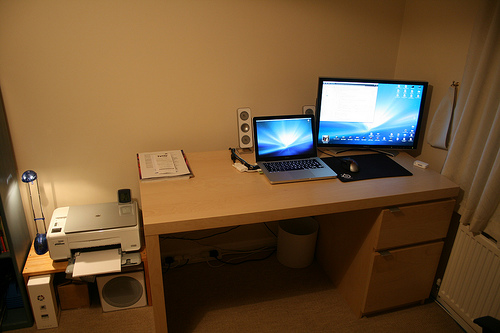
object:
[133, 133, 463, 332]
desk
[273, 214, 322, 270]
can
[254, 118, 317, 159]
monitors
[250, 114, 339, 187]
laptop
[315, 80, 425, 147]
monitor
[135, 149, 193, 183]
papers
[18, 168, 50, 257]
lamp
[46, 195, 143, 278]
printer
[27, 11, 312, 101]
wall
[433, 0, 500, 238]
curtains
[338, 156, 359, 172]
mouse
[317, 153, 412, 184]
pad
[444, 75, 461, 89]
hook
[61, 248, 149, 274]
tray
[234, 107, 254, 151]
speakers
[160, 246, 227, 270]
powerstrip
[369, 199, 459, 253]
drawers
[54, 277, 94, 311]
box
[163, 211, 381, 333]
shadow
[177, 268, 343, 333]
floor